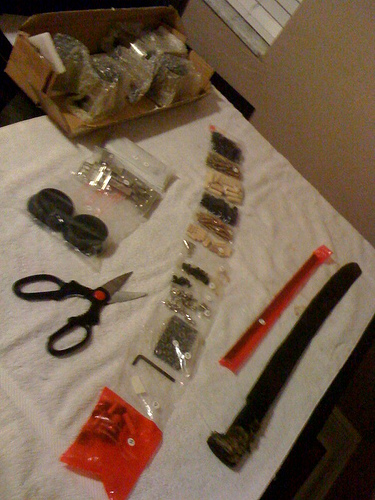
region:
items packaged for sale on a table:
[29, 124, 339, 484]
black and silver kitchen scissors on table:
[0, 266, 150, 349]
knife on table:
[203, 244, 371, 476]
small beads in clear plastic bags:
[153, 125, 251, 385]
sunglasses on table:
[22, 184, 110, 257]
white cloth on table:
[251, 101, 341, 231]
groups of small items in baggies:
[13, 9, 241, 116]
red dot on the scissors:
[89, 283, 117, 311]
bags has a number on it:
[114, 428, 145, 460]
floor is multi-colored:
[257, 23, 357, 167]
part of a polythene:
[102, 443, 118, 464]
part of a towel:
[199, 463, 219, 488]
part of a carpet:
[319, 434, 350, 475]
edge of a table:
[307, 408, 318, 440]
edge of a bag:
[153, 407, 167, 424]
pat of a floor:
[328, 427, 363, 476]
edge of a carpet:
[314, 445, 326, 468]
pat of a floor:
[349, 449, 365, 485]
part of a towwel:
[187, 441, 199, 458]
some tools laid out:
[21, 130, 367, 493]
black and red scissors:
[12, 264, 148, 353]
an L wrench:
[130, 353, 181, 384]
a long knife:
[202, 260, 364, 470]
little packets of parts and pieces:
[91, 123, 259, 498]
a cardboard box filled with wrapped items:
[3, 40, 248, 130]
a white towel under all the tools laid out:
[1, 78, 372, 498]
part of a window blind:
[201, 1, 319, 57]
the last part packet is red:
[54, 384, 175, 498]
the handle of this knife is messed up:
[199, 399, 275, 474]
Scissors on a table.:
[14, 257, 143, 352]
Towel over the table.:
[3, 362, 77, 438]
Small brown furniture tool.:
[122, 351, 180, 396]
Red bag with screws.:
[65, 391, 164, 493]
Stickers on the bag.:
[130, 369, 169, 415]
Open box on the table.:
[4, 4, 223, 114]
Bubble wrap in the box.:
[118, 40, 181, 90]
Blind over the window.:
[216, 0, 306, 56]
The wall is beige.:
[280, 58, 364, 139]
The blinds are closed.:
[217, 1, 307, 64]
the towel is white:
[153, 447, 170, 472]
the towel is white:
[187, 469, 196, 487]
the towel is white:
[179, 469, 192, 488]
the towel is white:
[183, 456, 194, 484]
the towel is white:
[175, 461, 185, 481]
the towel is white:
[171, 457, 180, 481]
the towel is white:
[190, 477, 199, 496]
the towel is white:
[185, 480, 206, 497]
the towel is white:
[192, 465, 210, 496]